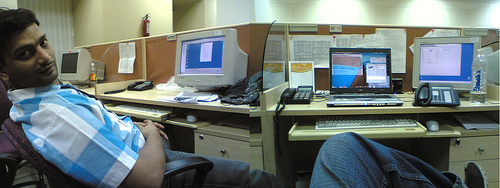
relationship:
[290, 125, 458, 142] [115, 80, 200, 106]
sliding tray under a desk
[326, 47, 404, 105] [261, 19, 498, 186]
laptop on a desk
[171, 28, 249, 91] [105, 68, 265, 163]
computer monitor on desk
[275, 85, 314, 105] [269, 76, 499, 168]
telephone on a desk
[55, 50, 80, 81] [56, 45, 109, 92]
computer screen on computer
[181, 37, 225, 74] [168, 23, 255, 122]
computer screen on computer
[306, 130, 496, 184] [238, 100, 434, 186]
person wearing jeans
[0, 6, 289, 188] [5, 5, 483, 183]
person sitting in office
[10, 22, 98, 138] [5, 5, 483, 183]
person sitting in office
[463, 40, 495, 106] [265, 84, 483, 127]
water bottle on desk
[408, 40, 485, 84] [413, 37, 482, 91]
computer screen on computer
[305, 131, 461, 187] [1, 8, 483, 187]
leg of person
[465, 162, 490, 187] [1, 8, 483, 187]
shoe of person